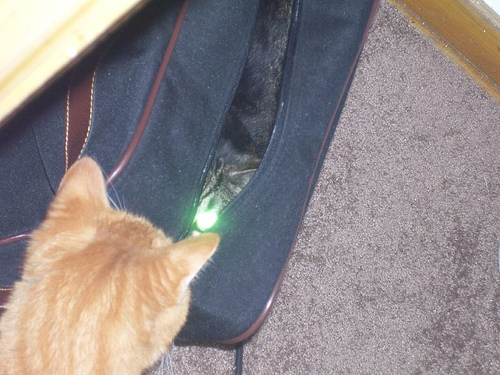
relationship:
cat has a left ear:
[6, 150, 226, 374] [154, 225, 225, 293]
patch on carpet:
[290, 283, 340, 329] [217, 0, 497, 374]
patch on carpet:
[398, 123, 438, 155] [141, 0, 498, 374]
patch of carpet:
[386, 146, 498, 270] [355, 134, 438, 327]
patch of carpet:
[398, 123, 438, 155] [401, 149, 441, 211]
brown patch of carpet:
[350, 87, 375, 119] [349, 32, 489, 366]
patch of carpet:
[364, 60, 438, 154] [252, 5, 498, 371]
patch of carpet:
[398, 123, 438, 155] [342, 133, 480, 340]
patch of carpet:
[398, 123, 438, 155] [141, 0, 498, 374]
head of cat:
[12, 150, 223, 374] [0, 156, 221, 375]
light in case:
[191, 195, 224, 237] [1, 1, 384, 358]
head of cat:
[12, 150, 223, 374] [0, 140, 227, 364]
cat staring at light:
[0, 156, 221, 375] [187, 189, 227, 234]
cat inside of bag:
[199, 10, 303, 207] [0, 0, 379, 344]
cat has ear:
[6, 150, 226, 374] [56, 164, 104, 206]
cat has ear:
[0, 156, 221, 375] [155, 227, 227, 299]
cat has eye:
[192, 0, 303, 204] [197, 209, 218, 229]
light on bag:
[191, 202, 224, 237] [106, 35, 312, 301]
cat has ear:
[6, 150, 226, 374] [46, 155, 109, 211]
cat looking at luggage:
[6, 150, 226, 374] [2, 0, 388, 352]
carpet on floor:
[95, 5, 496, 370] [147, 4, 499, 374]